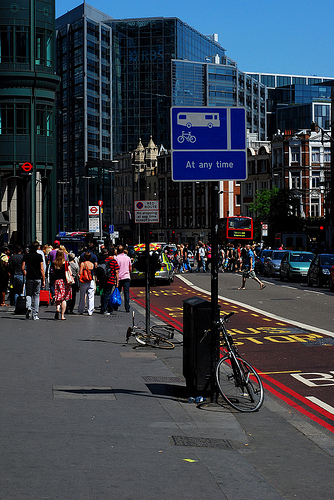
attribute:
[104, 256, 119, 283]
shirt — striped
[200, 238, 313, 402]
road — dark , grey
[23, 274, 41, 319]
jeans — blue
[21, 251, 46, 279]
shirt — black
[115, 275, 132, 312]
jeans — dark blue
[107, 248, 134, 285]
shirt — pink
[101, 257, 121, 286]
shirt — red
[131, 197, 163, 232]
sign — smaller